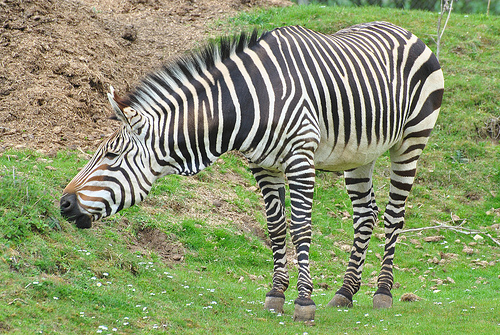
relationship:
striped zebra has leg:
[59, 19, 446, 320] [247, 163, 287, 312]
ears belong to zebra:
[100, 73, 157, 138] [33, 24, 434, 331]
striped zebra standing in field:
[59, 19, 446, 320] [1, 1, 497, 333]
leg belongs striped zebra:
[328, 162, 377, 307] [59, 19, 446, 320]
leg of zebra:
[371, 45, 444, 310] [15, 10, 472, 325]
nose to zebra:
[51, 197, 75, 213] [87, 25, 459, 307]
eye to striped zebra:
[102, 151, 119, 161] [59, 19, 446, 320]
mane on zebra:
[126, 22, 271, 117] [48, 13, 459, 323]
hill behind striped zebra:
[4, 8, 120, 74] [59, 19, 446, 320]